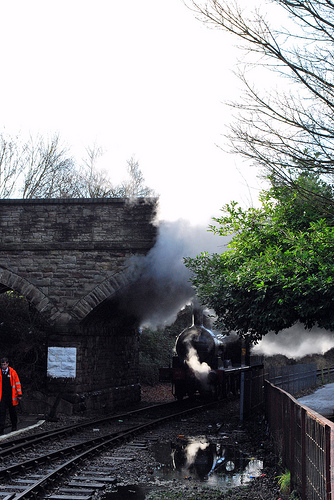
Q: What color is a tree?
A: Green.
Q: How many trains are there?
A: One.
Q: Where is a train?
A: On train tracks.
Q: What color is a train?
A: Black.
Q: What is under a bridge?
A: A train.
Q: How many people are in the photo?
A: One.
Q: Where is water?
A: On the ground.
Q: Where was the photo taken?
A: On the train tracks.